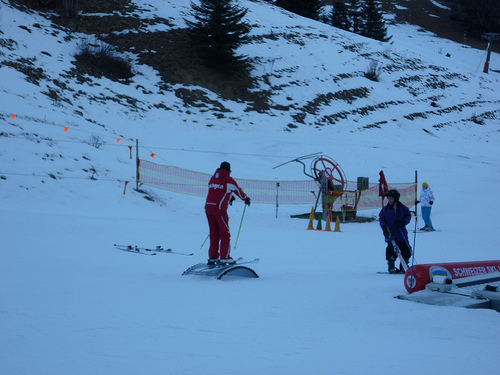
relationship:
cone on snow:
[305, 206, 315, 235] [279, 209, 388, 282]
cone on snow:
[315, 207, 323, 237] [279, 209, 388, 282]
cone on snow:
[322, 207, 334, 232] [279, 209, 388, 282]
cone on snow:
[333, 210, 344, 231] [279, 209, 388, 282]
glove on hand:
[242, 191, 253, 208] [242, 190, 255, 207]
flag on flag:
[4, 108, 158, 161] [4, 108, 158, 161]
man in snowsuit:
[204, 160, 253, 265] [204, 169, 246, 262]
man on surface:
[204, 160, 253, 265] [184, 254, 260, 284]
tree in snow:
[186, 3, 264, 102] [45, 3, 453, 158]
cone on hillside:
[305, 206, 315, 230] [0, 5, 448, 203]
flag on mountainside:
[4, 108, 158, 161] [20, 7, 464, 187]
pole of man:
[236, 196, 249, 253] [201, 162, 244, 265]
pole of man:
[193, 195, 228, 251] [201, 162, 244, 265]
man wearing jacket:
[204, 160, 253, 265] [200, 165, 253, 211]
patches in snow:
[71, 38, 143, 85] [43, 271, 324, 362]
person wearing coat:
[379, 186, 413, 275] [378, 201, 412, 238]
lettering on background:
[207, 180, 227, 189] [205, 168, 228, 201]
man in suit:
[204, 160, 253, 265] [204, 171, 247, 257]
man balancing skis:
[204, 160, 253, 265] [218, 257, 256, 272]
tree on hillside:
[186, 3, 264, 102] [0, 5, 448, 203]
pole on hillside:
[131, 136, 144, 187] [5, 10, 468, 228]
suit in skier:
[381, 199, 415, 273] [378, 188, 417, 268]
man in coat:
[204, 160, 253, 265] [416, 190, 436, 212]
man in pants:
[204, 160, 253, 265] [421, 206, 434, 227]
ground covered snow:
[2, 280, 452, 362] [161, 296, 290, 347]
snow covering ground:
[8, 240, 202, 368] [14, 297, 289, 373]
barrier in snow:
[141, 159, 410, 214] [48, 297, 391, 364]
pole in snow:
[134, 136, 141, 189] [12, 275, 322, 372]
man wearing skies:
[204, 160, 253, 265] [196, 193, 244, 255]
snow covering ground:
[51, 266, 322, 357] [11, 217, 471, 373]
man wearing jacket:
[204, 160, 253, 265] [204, 164, 250, 211]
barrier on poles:
[141, 159, 410, 214] [127, 136, 144, 182]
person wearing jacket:
[414, 179, 438, 231] [418, 187, 438, 209]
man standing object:
[204, 160, 253, 265] [404, 252, 482, 287]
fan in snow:
[310, 148, 353, 209] [2, 15, 498, 371]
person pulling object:
[379, 186, 413, 264] [397, 263, 498, 310]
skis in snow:
[117, 235, 173, 256] [2, 15, 498, 371]